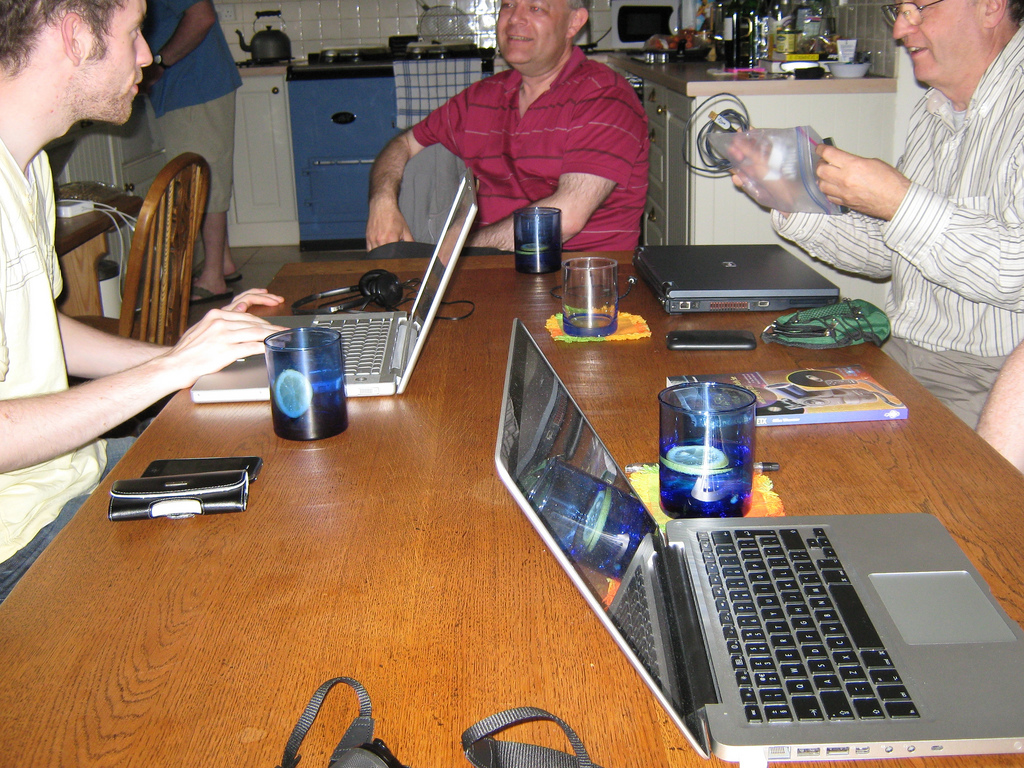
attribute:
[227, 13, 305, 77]
teapot — metal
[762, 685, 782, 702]
key — BLACK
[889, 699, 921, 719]
key — BLACK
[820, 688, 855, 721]
key — BLACK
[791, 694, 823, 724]
key — BLACK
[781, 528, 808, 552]
key — BLACK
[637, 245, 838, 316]
laptop — SILVER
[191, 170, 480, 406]
laptop — SILVER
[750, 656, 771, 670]
key — BLACK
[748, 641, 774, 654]
key — BLACK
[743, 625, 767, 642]
key — BLACK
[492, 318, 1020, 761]
laptop — SILVER